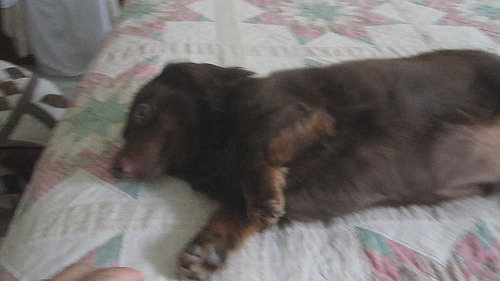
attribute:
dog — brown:
[111, 51, 499, 276]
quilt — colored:
[132, 11, 324, 56]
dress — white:
[39, 0, 84, 72]